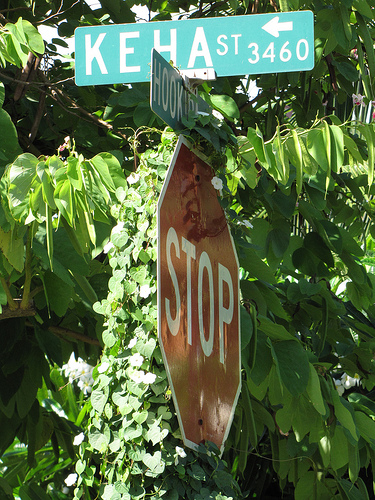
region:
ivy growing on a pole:
[71, 136, 180, 498]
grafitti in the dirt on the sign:
[156, 146, 231, 255]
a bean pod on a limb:
[44, 186, 54, 271]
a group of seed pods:
[254, 121, 346, 205]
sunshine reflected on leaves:
[68, 359, 167, 458]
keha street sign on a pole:
[66, 8, 326, 85]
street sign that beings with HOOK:
[147, 52, 229, 143]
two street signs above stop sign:
[41, 8, 329, 132]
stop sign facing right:
[144, 136, 261, 454]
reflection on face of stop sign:
[198, 389, 238, 445]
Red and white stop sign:
[151, 145, 261, 448]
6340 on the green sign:
[246, 41, 311, 67]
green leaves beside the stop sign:
[12, 149, 117, 313]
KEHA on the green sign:
[79, 31, 213, 73]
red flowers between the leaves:
[324, 77, 372, 122]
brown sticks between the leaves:
[45, 317, 103, 352]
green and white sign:
[74, 16, 309, 73]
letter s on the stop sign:
[162, 231, 183, 345]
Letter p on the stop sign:
[217, 262, 235, 371]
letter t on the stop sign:
[178, 238, 194, 359]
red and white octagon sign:
[151, 132, 246, 461]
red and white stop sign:
[147, 129, 248, 460]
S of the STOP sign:
[156, 221, 180, 342]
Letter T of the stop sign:
[180, 231, 195, 347]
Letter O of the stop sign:
[196, 249, 216, 358]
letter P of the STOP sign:
[215, 261, 233, 366]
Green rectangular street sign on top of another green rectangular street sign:
[68, 10, 320, 82]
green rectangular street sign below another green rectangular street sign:
[143, 48, 217, 143]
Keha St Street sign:
[71, 9, 318, 87]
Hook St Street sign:
[144, 40, 222, 142]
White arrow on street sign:
[258, 17, 293, 38]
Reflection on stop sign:
[181, 164, 205, 229]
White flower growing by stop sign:
[210, 177, 224, 190]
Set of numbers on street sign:
[247, 41, 309, 66]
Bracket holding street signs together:
[182, 70, 215, 82]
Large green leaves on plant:
[266, 335, 322, 433]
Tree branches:
[28, 63, 62, 126]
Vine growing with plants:
[268, 455, 304, 464]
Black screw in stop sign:
[197, 418, 204, 428]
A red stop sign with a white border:
[152, 135, 242, 456]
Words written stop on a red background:
[164, 226, 235, 365]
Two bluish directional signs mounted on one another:
[74, 9, 316, 135]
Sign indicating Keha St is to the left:
[75, 17, 314, 77]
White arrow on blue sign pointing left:
[260, 15, 295, 39]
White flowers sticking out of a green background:
[60, 349, 94, 397]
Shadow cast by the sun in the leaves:
[16, 88, 140, 157]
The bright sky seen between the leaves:
[44, 20, 75, 61]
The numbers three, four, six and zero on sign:
[246, 37, 311, 64]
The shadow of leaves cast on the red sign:
[181, 170, 223, 242]